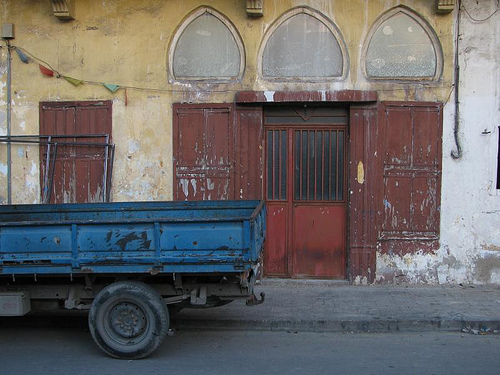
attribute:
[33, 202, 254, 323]
cart — blue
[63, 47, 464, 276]
building — covered, chipped, painted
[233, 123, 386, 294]
door — painted, red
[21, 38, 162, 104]
wall — painted, yellow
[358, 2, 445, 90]
window — arch-shaped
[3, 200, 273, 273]
truck bed — blue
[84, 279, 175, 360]
tire — black, worn out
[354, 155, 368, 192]
paint — chipped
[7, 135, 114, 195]
fencing — chain link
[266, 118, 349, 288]
door — metal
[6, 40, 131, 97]
flags — strung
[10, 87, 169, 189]
building siding — chipped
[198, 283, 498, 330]
sidewalk — grey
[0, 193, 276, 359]
pickup truck — very old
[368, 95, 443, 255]
shutter — red painted, fading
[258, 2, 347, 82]
window — oddly-shaped, dirty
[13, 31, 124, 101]
flags — multi-colored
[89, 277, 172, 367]
tire — old, dusty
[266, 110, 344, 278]
door — old, red, barred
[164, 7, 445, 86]
windows — odd, trio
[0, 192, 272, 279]
truck bed — blue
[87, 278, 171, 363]
truck wheel — rear, black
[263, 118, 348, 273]
door — rusty, metal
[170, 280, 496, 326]
sidewalk — grey, brick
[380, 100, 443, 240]
shutter — red, wooden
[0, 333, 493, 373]
road — black-top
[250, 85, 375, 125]
paint — peeling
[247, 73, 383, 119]
door — way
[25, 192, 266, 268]
bed — blue, truck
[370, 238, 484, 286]
paint — peeling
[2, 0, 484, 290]
building — old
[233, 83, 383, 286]
door — red, closed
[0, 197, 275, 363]
truck — blue, worn out, square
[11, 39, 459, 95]
line — electric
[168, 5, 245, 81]
window — triangular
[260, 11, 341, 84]
window — triangular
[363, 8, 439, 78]
window — triangular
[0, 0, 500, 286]
wall — yellow and white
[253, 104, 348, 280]
door — red, chipped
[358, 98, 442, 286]
door — red, chipped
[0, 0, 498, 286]
paint — white, chipped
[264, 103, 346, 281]
door — red, old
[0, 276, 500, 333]
sidewalk — gray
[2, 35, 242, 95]
banner — multicolored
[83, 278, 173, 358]
wheel — large, black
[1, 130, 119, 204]
poles — silver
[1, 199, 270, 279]
metal — blue, old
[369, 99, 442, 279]
door — old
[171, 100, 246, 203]
door — old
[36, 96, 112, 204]
door — old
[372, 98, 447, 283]
door — old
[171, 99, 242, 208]
door — old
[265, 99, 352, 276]
door — old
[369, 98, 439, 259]
door — old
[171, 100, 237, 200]
door — old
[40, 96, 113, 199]
door — old